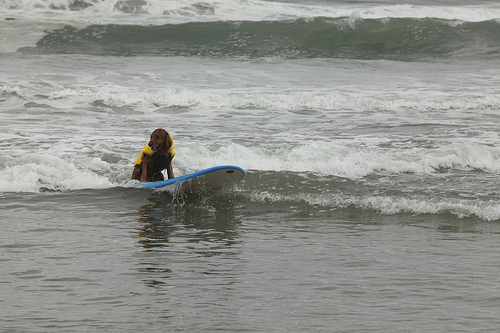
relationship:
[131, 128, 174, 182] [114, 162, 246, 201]
dog on surfboard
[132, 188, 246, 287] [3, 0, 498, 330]
reflection in water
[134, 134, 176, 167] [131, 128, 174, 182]
life jacket on dog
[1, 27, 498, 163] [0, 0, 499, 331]
wave in ocean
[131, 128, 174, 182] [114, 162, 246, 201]
dog sitting on surfboard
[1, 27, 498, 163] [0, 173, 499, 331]
wave heading toward shore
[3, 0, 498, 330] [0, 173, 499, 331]
water close to shore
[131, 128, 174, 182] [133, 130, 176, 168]
dog wearing life jacket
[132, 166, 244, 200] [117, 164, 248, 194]
bottom half of surfboard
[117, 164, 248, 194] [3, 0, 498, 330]
surfboard in water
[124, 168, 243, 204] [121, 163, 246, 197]
botton of surfboard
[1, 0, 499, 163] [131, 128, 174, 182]
wave behind dog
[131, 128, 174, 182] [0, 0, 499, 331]
dog in ocean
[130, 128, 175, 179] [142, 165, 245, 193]
surfer on surfboard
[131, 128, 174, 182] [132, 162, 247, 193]
dog on a surfboard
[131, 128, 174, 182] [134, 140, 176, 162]
dog wearing a life vest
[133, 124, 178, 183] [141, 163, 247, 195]
dog sitting on a surfboard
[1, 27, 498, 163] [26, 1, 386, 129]
wave in water